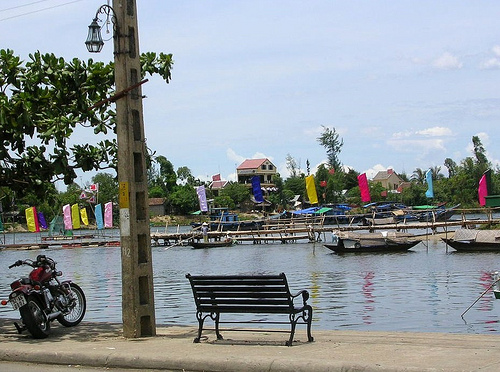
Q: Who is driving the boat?
A: No one.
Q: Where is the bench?
A: Near the lake.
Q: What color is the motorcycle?
A: Red.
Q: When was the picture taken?
A: Day time.